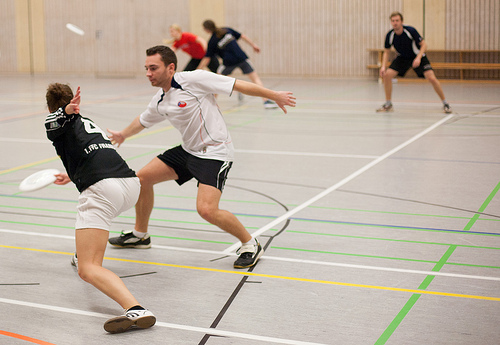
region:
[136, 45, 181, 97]
head of a person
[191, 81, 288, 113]
arm of a person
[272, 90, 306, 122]
hand of a person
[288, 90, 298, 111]
fingers of a person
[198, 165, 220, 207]
thigh of a person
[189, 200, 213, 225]
knee of a person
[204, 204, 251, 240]
leg of a person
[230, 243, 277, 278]
feet of a person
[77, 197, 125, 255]
thigh of a person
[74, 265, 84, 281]
knee of a person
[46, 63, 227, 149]
he is blocking her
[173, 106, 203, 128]
the shirt is white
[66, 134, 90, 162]
the shirt is black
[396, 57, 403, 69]
the shorts are black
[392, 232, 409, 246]
the line is bright green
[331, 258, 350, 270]
the line is white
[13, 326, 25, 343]
the line is orange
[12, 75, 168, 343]
person playing frisbee inside a building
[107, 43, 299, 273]
person playing frisbee inside a building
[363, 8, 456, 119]
person playing frisbee inside a building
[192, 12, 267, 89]
person playing frisbee inside a building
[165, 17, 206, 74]
person playing frisbee inside a building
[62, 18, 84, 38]
white frisbee flying through the air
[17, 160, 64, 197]
white frisbee in a persons hand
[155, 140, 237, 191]
pair of black and white shorts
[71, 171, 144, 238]
pair of white shorts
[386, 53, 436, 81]
pair of black shorts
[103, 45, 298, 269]
Man wearing white and black shirt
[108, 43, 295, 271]
Man wearing black and white shorts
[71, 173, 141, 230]
White shorts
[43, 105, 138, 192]
Black and white shirt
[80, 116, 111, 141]
White number on black shirt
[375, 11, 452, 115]
Man wearing black and white shirt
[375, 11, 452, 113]
Man wearing black and white shorts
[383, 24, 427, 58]
Black and white shirt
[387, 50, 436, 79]
Black and white shorts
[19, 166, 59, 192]
White frisbee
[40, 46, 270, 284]
the man is blocking the girl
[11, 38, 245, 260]
the man is blocking the girl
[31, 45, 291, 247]
the man is blocking the girl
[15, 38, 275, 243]
the man is blocking the girl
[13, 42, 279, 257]
the man is blocking the girl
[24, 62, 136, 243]
girl is holding a frisbee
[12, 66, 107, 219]
girl is holding a frisbee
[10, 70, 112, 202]
girl is holding a frisbee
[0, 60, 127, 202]
girl is holding a frisbee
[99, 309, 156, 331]
white shoe on the man playing frisbee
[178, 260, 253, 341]
a grey colored floor with different painted lines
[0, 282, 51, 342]
a grey colored floor with different painted lines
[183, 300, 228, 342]
a grey colored floor with different painted lines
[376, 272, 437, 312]
a grey colored floor with different painted lines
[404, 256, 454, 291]
a grey colored floor with different painted lines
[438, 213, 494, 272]
a grey colored floor with different painted lines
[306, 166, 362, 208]
a grey colored floor with different painted lines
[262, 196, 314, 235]
a grey colored floor with different painted lines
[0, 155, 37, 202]
a grey colored floor with different painted lines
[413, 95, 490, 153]
a grey colored floor with different painted lines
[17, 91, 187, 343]
A person bent over with a frisbee in their hand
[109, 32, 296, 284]
A man with his arms extended out to his sides.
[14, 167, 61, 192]
A white frisbee.